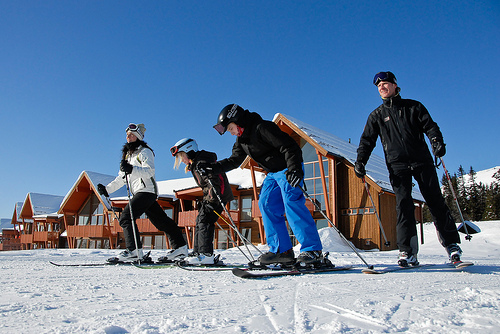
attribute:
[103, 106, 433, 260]
family — skiing, on vacation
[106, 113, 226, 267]
children — skiing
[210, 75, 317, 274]
mother — skiing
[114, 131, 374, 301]
skiers — having fun, four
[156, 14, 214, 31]
sky — bright, blue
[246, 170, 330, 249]
pants — blue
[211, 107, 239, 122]
helmet — black, blue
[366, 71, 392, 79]
goggles — black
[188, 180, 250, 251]
ski pole — silver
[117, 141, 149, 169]
scarf — fuzzy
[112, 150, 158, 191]
jacket — white, black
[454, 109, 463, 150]
clouds — white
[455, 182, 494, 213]
trees — pine